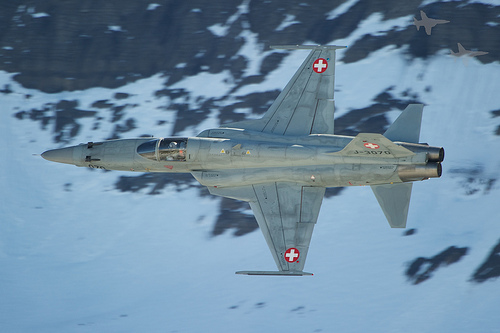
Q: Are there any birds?
A: No, there are no birds.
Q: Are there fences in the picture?
A: No, there are no fences.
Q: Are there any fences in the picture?
A: No, there are no fences.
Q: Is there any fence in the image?
A: No, there are no fences.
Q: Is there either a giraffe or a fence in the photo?
A: No, there are no fences or giraffes.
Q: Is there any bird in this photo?
A: No, there are no birds.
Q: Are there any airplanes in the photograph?
A: Yes, there is an airplane.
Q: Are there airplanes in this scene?
A: Yes, there is an airplane.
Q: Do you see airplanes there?
A: Yes, there is an airplane.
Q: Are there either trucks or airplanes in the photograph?
A: Yes, there is an airplane.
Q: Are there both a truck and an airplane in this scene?
A: No, there is an airplane but no trucks.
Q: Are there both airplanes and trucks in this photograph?
A: No, there is an airplane but no trucks.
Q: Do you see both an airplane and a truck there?
A: No, there is an airplane but no trucks.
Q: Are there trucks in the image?
A: No, there are no trucks.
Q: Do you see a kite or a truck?
A: No, there are no trucks or kites.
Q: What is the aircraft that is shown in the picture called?
A: The aircraft is an airplane.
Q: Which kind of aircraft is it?
A: The aircraft is an airplane.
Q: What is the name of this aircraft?
A: This is an airplane.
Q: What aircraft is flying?
A: The aircraft is an airplane.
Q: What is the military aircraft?
A: The aircraft is an airplane.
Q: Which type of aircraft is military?
A: The aircraft is an airplane.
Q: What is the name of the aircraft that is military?
A: The aircraft is an airplane.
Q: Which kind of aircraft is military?
A: The aircraft is an airplane.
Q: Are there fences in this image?
A: No, there are no fences.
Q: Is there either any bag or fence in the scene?
A: No, there are no fences or bags.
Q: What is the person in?
A: The person is in the cockpit.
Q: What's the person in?
A: The person is in the cockpit.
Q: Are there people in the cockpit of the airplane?
A: Yes, there is a person in the cockpit.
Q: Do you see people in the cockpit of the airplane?
A: Yes, there is a person in the cockpit.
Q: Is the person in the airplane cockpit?
A: Yes, the person is in the cockpit.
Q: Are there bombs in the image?
A: No, there are no bombs.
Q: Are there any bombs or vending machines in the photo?
A: No, there are no bombs or vending machines.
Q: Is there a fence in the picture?
A: No, there are no fences.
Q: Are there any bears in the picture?
A: No, there are no bears.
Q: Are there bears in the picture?
A: No, there are no bears.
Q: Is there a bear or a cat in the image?
A: No, there are no bears or cats.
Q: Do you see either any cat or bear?
A: No, there are no bears or cats.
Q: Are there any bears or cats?
A: No, there are no bears or cats.